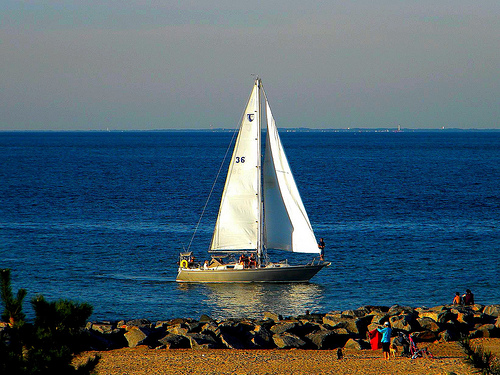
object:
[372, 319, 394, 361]
person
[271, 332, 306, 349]
rocks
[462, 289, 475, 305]
people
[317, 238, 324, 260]
person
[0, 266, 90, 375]
tree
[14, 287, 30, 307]
branch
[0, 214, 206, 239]
reflection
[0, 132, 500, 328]
waves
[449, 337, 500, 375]
grass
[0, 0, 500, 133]
clouds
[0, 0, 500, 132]
sky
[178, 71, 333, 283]
sailboat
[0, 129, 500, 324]
ocean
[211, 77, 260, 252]
masts